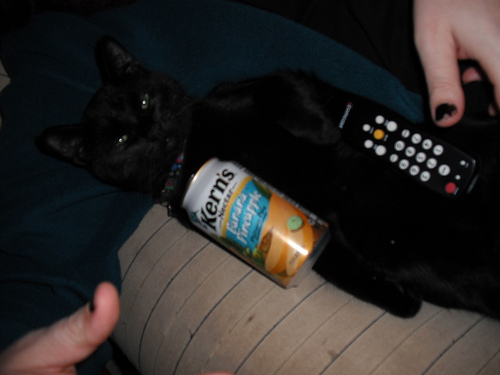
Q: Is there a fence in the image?
A: No, there are no fences.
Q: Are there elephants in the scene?
A: No, there are no elephants.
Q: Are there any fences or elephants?
A: No, there are no elephants or fences.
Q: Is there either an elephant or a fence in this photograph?
A: No, there are no elephants or fences.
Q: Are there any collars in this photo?
A: Yes, there is a collar.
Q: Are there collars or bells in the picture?
A: Yes, there is a collar.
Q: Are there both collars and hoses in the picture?
A: No, there is a collar but no hoses.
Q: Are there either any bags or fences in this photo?
A: No, there are no fences or bags.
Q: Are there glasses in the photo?
A: No, there are no glasses.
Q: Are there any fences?
A: No, there are no fences.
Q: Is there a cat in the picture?
A: Yes, there is a cat.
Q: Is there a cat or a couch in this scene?
A: Yes, there is a cat.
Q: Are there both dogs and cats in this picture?
A: No, there is a cat but no dogs.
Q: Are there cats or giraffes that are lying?
A: Yes, the cat is lying.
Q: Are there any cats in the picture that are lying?
A: Yes, there is a cat that is lying.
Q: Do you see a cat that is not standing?
A: Yes, there is a cat that is lying .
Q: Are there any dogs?
A: No, there are no dogs.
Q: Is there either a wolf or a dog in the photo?
A: No, there are no dogs or wolves.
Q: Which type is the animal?
A: The animal is a cat.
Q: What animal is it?
A: The animal is a cat.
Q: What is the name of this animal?
A: This is a cat.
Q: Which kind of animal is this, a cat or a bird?
A: This is a cat.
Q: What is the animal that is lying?
A: The animal is a cat.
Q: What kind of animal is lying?
A: The animal is a cat.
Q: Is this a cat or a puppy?
A: This is a cat.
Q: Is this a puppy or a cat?
A: This is a cat.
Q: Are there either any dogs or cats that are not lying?
A: No, there is a cat but it is lying.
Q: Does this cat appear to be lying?
A: Yes, the cat is lying.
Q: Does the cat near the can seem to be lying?
A: Yes, the cat is lying.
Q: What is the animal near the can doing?
A: The cat is lying.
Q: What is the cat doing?
A: The cat is lying.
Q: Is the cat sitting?
A: No, the cat is lying.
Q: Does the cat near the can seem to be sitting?
A: No, the cat is lying.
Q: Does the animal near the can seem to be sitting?
A: No, the cat is lying.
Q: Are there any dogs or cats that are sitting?
A: No, there is a cat but it is lying.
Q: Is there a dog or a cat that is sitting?
A: No, there is a cat but it is lying.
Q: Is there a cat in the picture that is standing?
A: No, there is a cat but it is lying.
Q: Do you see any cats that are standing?
A: No, there is a cat but it is lying.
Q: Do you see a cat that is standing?
A: No, there is a cat but it is lying.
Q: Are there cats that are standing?
A: No, there is a cat but it is lying.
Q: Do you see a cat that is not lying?
A: No, there is a cat but it is lying.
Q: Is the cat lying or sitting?
A: The cat is lying.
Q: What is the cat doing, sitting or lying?
A: The cat is lying.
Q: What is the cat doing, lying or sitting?
A: The cat is lying.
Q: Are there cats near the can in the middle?
A: Yes, there is a cat near the can.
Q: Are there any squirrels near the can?
A: No, there is a cat near the can.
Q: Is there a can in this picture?
A: Yes, there is a can.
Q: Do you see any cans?
A: Yes, there is a can.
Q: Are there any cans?
A: Yes, there is a can.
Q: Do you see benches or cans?
A: Yes, there is a can.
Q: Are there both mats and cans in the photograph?
A: No, there is a can but no mats.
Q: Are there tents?
A: No, there are no tents.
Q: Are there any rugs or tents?
A: No, there are no tents or rugs.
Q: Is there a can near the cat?
A: Yes, there is a can near the cat.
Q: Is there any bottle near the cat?
A: No, there is a can near the cat.